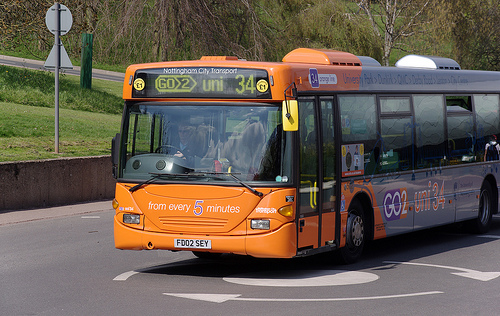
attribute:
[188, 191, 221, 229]
number — side, white, 5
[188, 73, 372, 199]
bus — multi colored, here, traveling, orange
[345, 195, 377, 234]
wheel — here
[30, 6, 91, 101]
sign — here, side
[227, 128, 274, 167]
driver — here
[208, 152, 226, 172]
object — red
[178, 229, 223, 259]
plate — license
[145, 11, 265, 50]
trees — here, dead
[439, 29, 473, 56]
leaves — green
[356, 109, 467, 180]
windows — glass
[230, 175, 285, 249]
headlights — here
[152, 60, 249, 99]
display — yellow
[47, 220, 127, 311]
asphault — black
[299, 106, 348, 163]
doors — glass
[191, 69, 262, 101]
lettering — yellow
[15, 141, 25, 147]
grass — green, short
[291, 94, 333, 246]
door — closed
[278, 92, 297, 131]
mirror — yellow, side